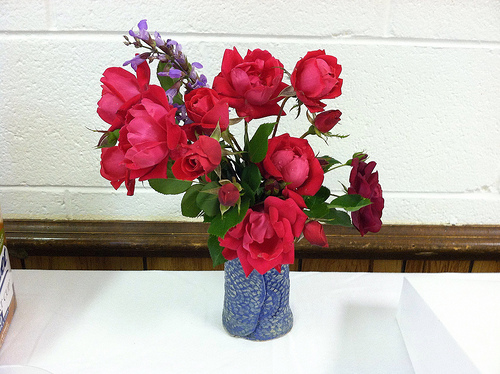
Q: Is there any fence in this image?
A: No, there are no fences.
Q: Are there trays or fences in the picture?
A: No, there are no fences or trays.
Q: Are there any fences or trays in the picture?
A: No, there are no fences or trays.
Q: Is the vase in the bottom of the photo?
A: Yes, the vase is in the bottom of the image.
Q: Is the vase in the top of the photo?
A: No, the vase is in the bottom of the image.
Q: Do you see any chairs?
A: No, there are no chairs.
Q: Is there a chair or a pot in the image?
A: No, there are no chairs or pots.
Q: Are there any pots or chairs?
A: No, there are no chairs or pots.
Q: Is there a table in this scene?
A: Yes, there is a table.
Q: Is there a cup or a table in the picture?
A: Yes, there is a table.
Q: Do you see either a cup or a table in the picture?
A: Yes, there is a table.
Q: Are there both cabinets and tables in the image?
A: No, there is a table but no cabinets.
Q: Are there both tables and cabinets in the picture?
A: No, there is a table but no cabinets.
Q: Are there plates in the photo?
A: No, there are no plates.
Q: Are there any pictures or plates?
A: No, there are no plates or pictures.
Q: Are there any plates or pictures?
A: No, there are no plates or pictures.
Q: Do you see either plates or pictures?
A: No, there are no plates or pictures.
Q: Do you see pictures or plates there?
A: No, there are no plates or pictures.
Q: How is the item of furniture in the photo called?
A: The piece of furniture is a table.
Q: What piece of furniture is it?
A: The piece of furniture is a table.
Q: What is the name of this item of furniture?
A: This is a table.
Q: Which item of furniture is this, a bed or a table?
A: This is a table.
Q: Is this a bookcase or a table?
A: This is a table.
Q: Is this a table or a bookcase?
A: This is a table.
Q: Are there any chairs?
A: No, there are no chairs.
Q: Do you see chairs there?
A: No, there are no chairs.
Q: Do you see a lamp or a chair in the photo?
A: No, there are no chairs or lamps.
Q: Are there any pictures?
A: No, there are no pictures.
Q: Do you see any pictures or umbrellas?
A: No, there are no pictures or umbrellas.